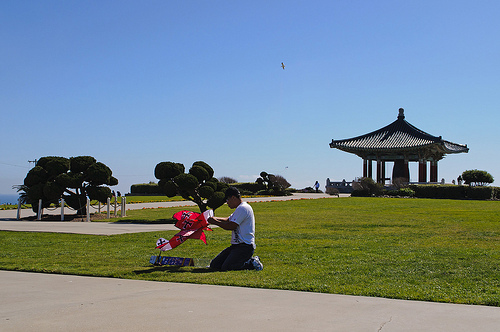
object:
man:
[206, 186, 265, 272]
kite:
[153, 208, 215, 252]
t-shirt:
[227, 203, 257, 246]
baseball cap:
[219, 186, 241, 205]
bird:
[279, 60, 287, 70]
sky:
[1, 0, 499, 201]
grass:
[0, 199, 498, 305]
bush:
[21, 154, 118, 218]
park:
[0, 106, 499, 330]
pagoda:
[326, 106, 470, 194]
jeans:
[207, 242, 254, 271]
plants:
[247, 198, 332, 210]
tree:
[153, 160, 229, 211]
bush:
[408, 182, 492, 201]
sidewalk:
[0, 266, 499, 331]